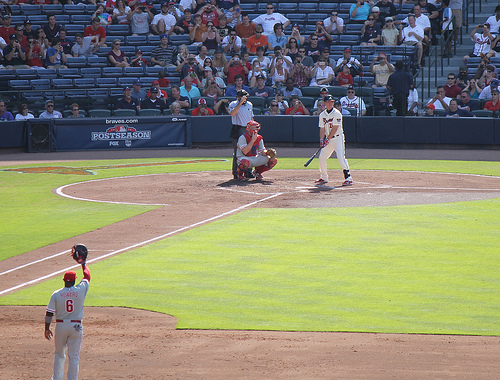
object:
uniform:
[318, 107, 353, 183]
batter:
[314, 94, 354, 186]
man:
[369, 52, 395, 87]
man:
[424, 85, 452, 110]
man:
[285, 95, 311, 115]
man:
[463, 21, 495, 63]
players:
[227, 88, 255, 179]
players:
[43, 261, 91, 379]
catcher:
[236, 120, 279, 181]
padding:
[236, 132, 278, 178]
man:
[166, 86, 190, 109]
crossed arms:
[167, 98, 194, 108]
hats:
[123, 86, 158, 93]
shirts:
[116, 96, 167, 109]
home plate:
[295, 184, 337, 193]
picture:
[0, 0, 498, 377]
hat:
[323, 95, 335, 102]